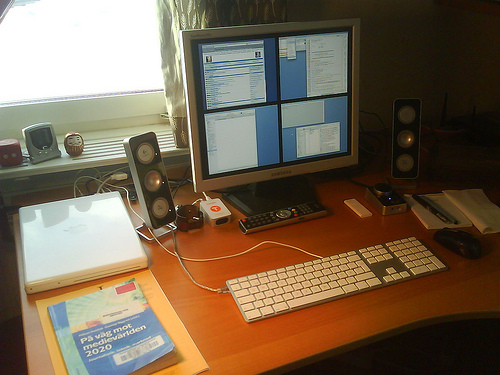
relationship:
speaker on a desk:
[119, 127, 181, 253] [13, 166, 498, 373]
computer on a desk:
[174, 17, 364, 217] [13, 166, 498, 373]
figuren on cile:
[56, 117, 95, 164] [1, 97, 198, 189]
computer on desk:
[158, 25, 373, 196] [0, 153, 467, 373]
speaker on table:
[123, 130, 177, 229] [12, 157, 480, 362]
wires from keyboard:
[74, 162, 322, 289] [181, 214, 480, 331]